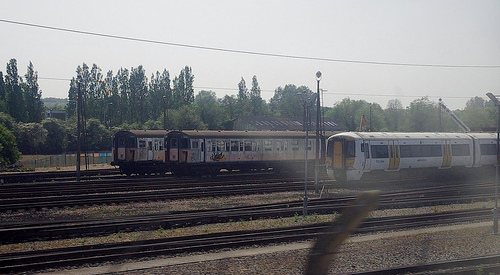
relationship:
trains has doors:
[326, 123, 500, 182] [330, 137, 456, 177]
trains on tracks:
[110, 123, 500, 186] [3, 161, 500, 266]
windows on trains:
[368, 141, 500, 157] [326, 123, 500, 182]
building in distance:
[235, 117, 354, 139] [2, 31, 500, 202]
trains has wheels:
[326, 123, 500, 182] [367, 163, 499, 186]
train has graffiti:
[164, 128, 328, 179] [201, 143, 297, 165]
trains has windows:
[326, 123, 500, 182] [368, 141, 500, 157]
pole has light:
[67, 71, 92, 190] [75, 75, 83, 83]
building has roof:
[235, 117, 354, 139] [238, 117, 344, 131]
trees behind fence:
[36, 84, 323, 164] [36, 84, 323, 164]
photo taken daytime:
[19, 10, 407, 261] [1, 3, 499, 268]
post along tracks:
[301, 86, 342, 167] [41, 86, 342, 256]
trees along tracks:
[68, 84, 495, 141] [68, 84, 495, 261]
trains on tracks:
[326, 123, 500, 182] [2, 116, 493, 256]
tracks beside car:
[88, 143, 486, 261] [88, 143, 486, 261]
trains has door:
[326, 123, 500, 182] [366, 143, 420, 187]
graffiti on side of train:
[176, 133, 310, 175] [164, 128, 328, 179]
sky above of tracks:
[25, 9, 355, 113] [25, 150, 355, 251]